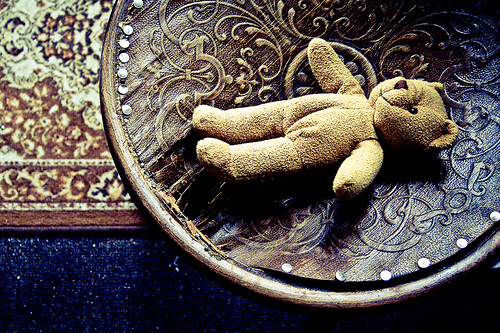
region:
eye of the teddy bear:
[406, 103, 419, 115]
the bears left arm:
[337, 158, 377, 193]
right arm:
[302, 37, 348, 84]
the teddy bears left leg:
[191, 138, 283, 175]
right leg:
[188, 100, 260, 138]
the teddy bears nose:
[391, 80, 408, 91]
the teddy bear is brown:
[177, 35, 454, 189]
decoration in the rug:
[16, 158, 94, 202]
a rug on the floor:
[1, 57, 102, 157]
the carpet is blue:
[57, 262, 132, 326]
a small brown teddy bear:
[188, 33, 445, 214]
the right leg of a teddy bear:
[201, 98, 269, 132]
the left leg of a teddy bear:
[184, 125, 289, 185]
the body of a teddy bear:
[274, 83, 365, 161]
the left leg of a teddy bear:
[337, 141, 381, 195]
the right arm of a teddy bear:
[290, 29, 347, 97]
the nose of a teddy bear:
[394, 66, 416, 103]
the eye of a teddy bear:
[404, 99, 416, 117]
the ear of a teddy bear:
[434, 103, 466, 153]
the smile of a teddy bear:
[370, 85, 400, 112]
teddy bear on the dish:
[146, 25, 463, 198]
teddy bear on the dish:
[163, 33, 456, 243]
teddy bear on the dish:
[142, 24, 484, 279]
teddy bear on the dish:
[156, 22, 479, 242]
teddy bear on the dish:
[123, 22, 452, 242]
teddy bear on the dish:
[158, 35, 456, 235]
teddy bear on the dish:
[157, 31, 442, 223]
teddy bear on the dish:
[158, 40, 455, 212]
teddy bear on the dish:
[167, 40, 453, 238]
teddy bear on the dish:
[128, 39, 465, 204]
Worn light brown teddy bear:
[190, 35, 458, 196]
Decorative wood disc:
[97, 0, 497, 309]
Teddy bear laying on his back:
[192, 34, 459, 200]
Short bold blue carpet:
[0, 222, 498, 331]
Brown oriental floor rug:
[0, 0, 158, 233]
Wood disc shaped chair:
[97, 0, 499, 310]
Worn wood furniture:
[98, 0, 498, 311]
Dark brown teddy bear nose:
[391, 77, 408, 92]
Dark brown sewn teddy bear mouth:
[376, 84, 393, 107]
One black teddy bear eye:
[402, 102, 420, 117]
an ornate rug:
[0, 8, 148, 240]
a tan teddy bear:
[172, 29, 453, 217]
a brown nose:
[391, 73, 418, 98]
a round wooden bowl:
[85, 1, 486, 318]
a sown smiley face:
[376, 78, 395, 109]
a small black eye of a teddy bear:
[405, 98, 422, 118]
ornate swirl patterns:
[139, 3, 280, 101]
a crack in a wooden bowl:
[257, 240, 499, 290]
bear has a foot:
[191, 106, 229, 136]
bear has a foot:
[194, 136, 234, 175]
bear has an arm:
[329, 138, 386, 195]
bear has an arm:
[307, 35, 359, 91]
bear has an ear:
[430, 119, 459, 149]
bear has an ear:
[428, 81, 444, 97]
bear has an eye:
[408, 102, 418, 114]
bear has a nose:
[395, 79, 408, 91]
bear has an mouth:
[381, 85, 401, 107]